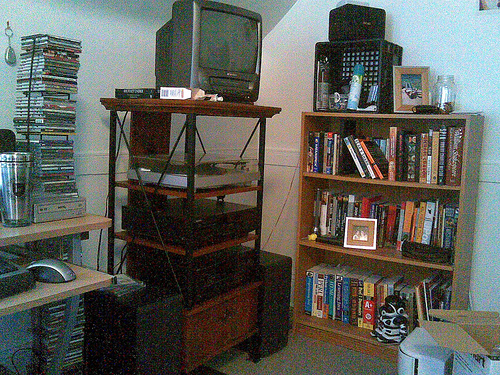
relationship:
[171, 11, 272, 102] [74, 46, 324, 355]
tv on shelf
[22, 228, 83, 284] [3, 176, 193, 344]
mouse on desk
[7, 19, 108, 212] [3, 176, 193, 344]
cds on desk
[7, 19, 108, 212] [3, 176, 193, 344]
cds under desk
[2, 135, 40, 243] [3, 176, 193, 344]
cup on desk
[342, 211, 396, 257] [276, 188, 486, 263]
picture on shelf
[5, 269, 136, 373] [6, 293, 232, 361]
computer on ground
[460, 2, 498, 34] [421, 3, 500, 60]
window in wall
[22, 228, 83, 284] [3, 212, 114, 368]
mouse on desk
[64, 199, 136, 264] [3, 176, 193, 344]
edge of desk